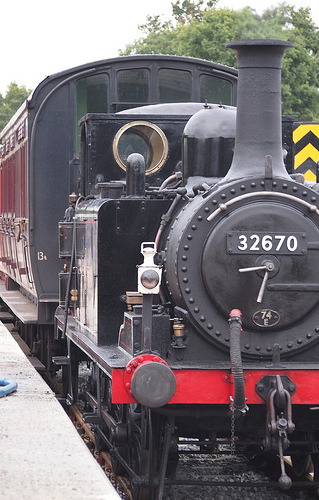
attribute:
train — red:
[2, 38, 318, 498]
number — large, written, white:
[232, 230, 302, 254]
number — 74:
[249, 306, 281, 326]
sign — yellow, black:
[284, 116, 316, 195]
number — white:
[237, 234, 244, 250]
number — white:
[246, 233, 258, 251]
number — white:
[259, 233, 270, 249]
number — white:
[273, 233, 283, 250]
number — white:
[286, 234, 302, 251]